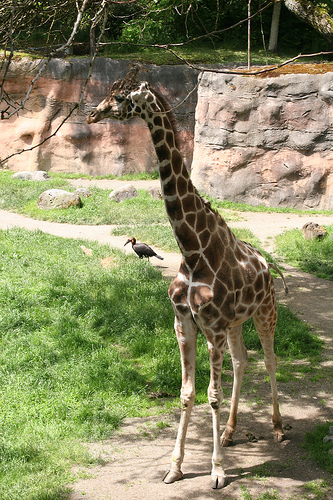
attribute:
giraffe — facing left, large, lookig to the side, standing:
[86, 63, 289, 488]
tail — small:
[267, 264, 289, 295]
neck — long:
[144, 112, 231, 274]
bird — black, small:
[124, 236, 165, 265]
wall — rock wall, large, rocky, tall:
[0, 59, 333, 210]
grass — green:
[1, 170, 169, 224]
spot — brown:
[163, 198, 184, 221]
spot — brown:
[154, 144, 170, 164]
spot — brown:
[199, 231, 210, 247]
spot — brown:
[219, 228, 230, 247]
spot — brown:
[242, 287, 254, 306]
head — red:
[124, 236, 136, 246]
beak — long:
[124, 240, 129, 247]